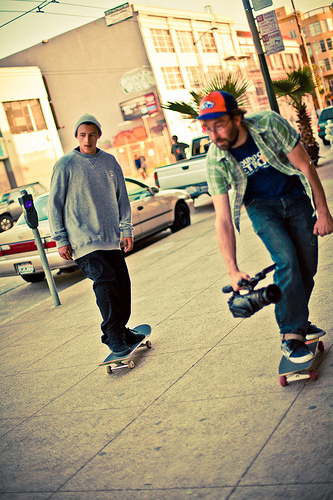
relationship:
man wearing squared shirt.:
[196, 86, 332, 361] [194, 109, 326, 232]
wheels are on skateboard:
[278, 338, 327, 388] [279, 338, 326, 387]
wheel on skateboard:
[146, 340, 152, 349] [100, 322, 162, 374]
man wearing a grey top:
[48, 114, 149, 356] [45, 145, 135, 261]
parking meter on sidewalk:
[16, 189, 66, 309] [0, 163, 332, 497]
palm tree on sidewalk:
[271, 69, 332, 168] [0, 163, 332, 497]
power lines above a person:
[0, 0, 332, 79] [167, 132, 192, 167]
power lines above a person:
[0, 0, 332, 79] [128, 151, 160, 185]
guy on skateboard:
[196, 86, 332, 361] [279, 338, 326, 387]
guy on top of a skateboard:
[48, 114, 149, 356] [100, 322, 162, 374]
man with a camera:
[196, 86, 332, 361] [218, 262, 287, 319]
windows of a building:
[151, 26, 219, 58] [0, 3, 264, 193]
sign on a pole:
[255, 10, 289, 57] [240, 0, 297, 117]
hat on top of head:
[194, 93, 245, 120] [195, 92, 246, 151]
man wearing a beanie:
[48, 114, 149, 356] [72, 114, 102, 139]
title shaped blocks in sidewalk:
[1, 182, 333, 499] [0, 163, 332, 497]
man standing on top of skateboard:
[196, 86, 332, 361] [279, 338, 326, 387]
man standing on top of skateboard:
[48, 114, 149, 356] [100, 322, 162, 374]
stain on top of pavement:
[153, 441, 168, 455] [0, 163, 332, 497]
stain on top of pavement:
[194, 409, 211, 425] [0, 163, 332, 497]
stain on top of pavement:
[95, 448, 109, 459] [0, 163, 332, 497]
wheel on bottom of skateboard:
[127, 358, 139, 371] [100, 322, 162, 374]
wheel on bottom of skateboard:
[104, 365, 113, 379] [100, 322, 162, 374]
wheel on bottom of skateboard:
[144, 339, 153, 349] [100, 322, 162, 374]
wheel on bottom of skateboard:
[277, 377, 291, 388] [279, 338, 326, 387]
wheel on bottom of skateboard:
[309, 369, 323, 379] [279, 338, 326, 387]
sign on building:
[103, 2, 133, 26] [0, 3, 264, 193]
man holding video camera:
[196, 86, 332, 361] [218, 262, 287, 319]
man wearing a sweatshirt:
[48, 114, 149, 356] [45, 145, 135, 261]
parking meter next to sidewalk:
[16, 189, 66, 309] [0, 163, 332, 497]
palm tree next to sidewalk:
[271, 69, 332, 168] [0, 163, 332, 497]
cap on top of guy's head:
[72, 114, 102, 139] [67, 113, 107, 153]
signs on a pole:
[255, 10, 289, 57] [240, 0, 297, 117]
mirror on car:
[148, 186, 161, 196] [0, 177, 196, 283]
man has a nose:
[196, 86, 332, 361] [208, 128, 221, 142]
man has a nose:
[48, 114, 149, 356] [83, 134, 93, 146]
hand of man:
[120, 234, 136, 255] [48, 114, 149, 356]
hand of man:
[58, 243, 72, 266] [48, 114, 149, 356]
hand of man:
[312, 213, 333, 238] [196, 86, 332, 361]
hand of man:
[230, 271, 251, 290] [196, 86, 332, 361]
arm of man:
[268, 110, 332, 234] [196, 86, 332, 361]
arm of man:
[200, 151, 253, 291] [196, 86, 332, 361]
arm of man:
[47, 159, 74, 264] [48, 114, 149, 356]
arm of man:
[108, 154, 136, 252] [48, 114, 149, 356]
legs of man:
[245, 218, 332, 339] [196, 86, 332, 361]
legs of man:
[74, 256, 133, 338] [48, 114, 149, 356]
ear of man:
[230, 114, 244, 126] [196, 86, 332, 361]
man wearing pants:
[48, 114, 149, 356] [73, 238, 139, 346]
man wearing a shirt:
[196, 86, 332, 361] [194, 109, 326, 232]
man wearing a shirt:
[48, 114, 149, 356] [45, 145, 135, 261]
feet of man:
[283, 321, 328, 368] [196, 86, 332, 361]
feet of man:
[102, 331, 144, 354] [48, 114, 149, 356]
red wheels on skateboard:
[279, 338, 326, 387] [276, 326, 326, 385]